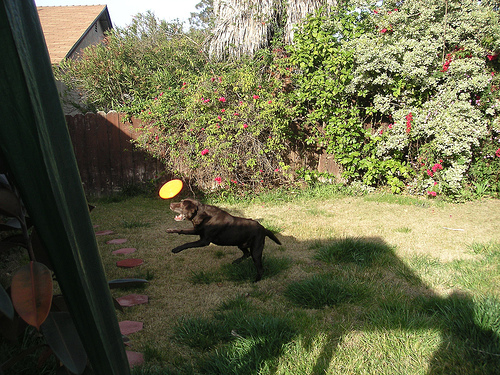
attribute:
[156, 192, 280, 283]
dog — large, black, jumping, big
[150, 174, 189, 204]
frisbee — in flight, yellow, in air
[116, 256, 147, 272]
stone — for stepping, red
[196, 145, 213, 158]
flower — reddish pink, pink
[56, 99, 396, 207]
fence — brown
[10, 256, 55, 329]
leaf — orange, green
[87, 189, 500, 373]
yard — green, light, dark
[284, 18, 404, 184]
leaves — green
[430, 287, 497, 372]
shadow — of person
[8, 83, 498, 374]
back yard — back yard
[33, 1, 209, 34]
sky — white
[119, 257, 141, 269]
frisbee — red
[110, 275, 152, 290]
stone — concrete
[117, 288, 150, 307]
stone — for stepping, concrete